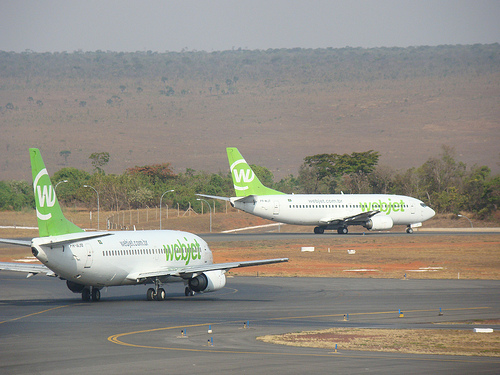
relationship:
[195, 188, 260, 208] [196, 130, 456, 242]
tail wing on jetliner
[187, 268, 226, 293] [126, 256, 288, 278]
engine on wing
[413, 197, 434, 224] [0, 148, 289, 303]
cock pit on jet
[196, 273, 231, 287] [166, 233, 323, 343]
engine under wing